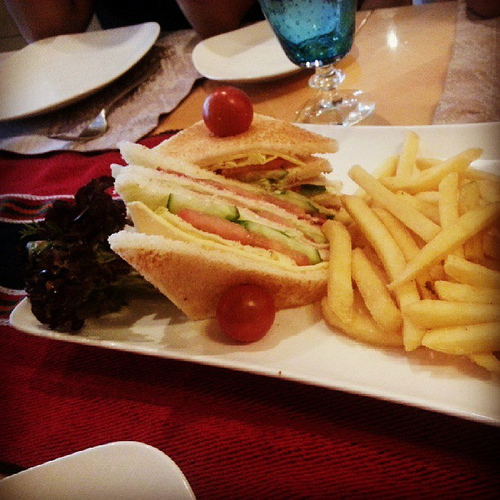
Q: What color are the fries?
A: Yellow.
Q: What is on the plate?
A: A sandwich.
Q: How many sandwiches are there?
A: One.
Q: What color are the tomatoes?
A: Red.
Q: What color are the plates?
A: White.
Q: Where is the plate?
A: On the table.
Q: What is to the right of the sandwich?
A: The fries.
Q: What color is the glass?
A: Blue.